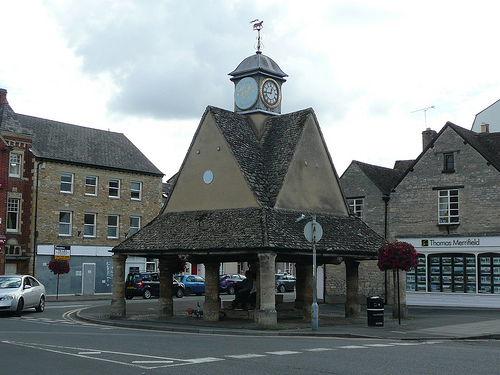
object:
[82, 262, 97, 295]
door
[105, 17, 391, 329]
building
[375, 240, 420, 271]
flowers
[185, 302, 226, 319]
bike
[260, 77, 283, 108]
clock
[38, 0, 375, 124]
rain cloud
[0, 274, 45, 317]
car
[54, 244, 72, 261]
sign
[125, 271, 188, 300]
car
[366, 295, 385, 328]
can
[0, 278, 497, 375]
roundabout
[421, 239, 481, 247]
sign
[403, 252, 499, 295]
window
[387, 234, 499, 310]
shop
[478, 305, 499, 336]
corner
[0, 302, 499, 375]
street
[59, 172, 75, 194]
window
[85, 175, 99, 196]
window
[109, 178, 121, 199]
window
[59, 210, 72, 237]
window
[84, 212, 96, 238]
window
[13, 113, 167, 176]
roof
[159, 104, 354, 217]
roof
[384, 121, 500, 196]
roof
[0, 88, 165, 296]
brick building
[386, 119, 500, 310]
brick building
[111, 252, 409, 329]
columns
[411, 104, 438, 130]
antenna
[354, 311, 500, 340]
sidewalk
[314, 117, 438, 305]
building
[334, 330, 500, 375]
road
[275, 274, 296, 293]
car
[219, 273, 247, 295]
car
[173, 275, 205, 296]
car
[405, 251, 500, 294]
storefront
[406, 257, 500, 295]
photos